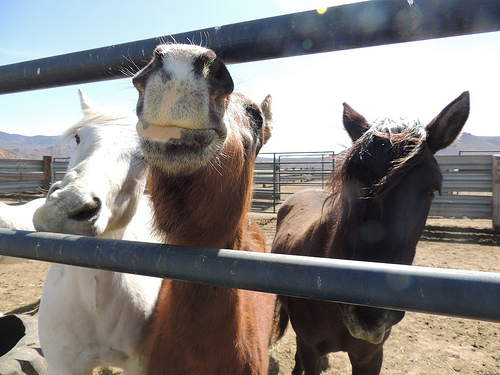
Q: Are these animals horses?
A: Yes, all the animals are horses.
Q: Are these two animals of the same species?
A: Yes, all the animals are horses.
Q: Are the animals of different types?
A: No, all the animals are horses.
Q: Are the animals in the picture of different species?
A: No, all the animals are horses.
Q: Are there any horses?
A: Yes, there is a horse.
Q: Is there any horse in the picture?
A: Yes, there is a horse.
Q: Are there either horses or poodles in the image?
A: Yes, there is a horse.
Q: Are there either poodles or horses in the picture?
A: Yes, there is a horse.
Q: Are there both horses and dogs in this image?
A: No, there is a horse but no dogs.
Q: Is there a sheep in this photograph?
A: No, there is no sheep.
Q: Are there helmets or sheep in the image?
A: No, there are no sheep or helmets.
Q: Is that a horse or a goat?
A: That is a horse.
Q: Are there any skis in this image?
A: No, there are no skis.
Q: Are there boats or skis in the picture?
A: No, there are no skis or boats.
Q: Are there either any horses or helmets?
A: Yes, there is a horse.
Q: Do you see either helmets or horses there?
A: Yes, there is a horse.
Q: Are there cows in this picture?
A: No, there are no cows.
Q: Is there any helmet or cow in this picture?
A: No, there are no cows or helmets.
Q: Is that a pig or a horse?
A: That is a horse.